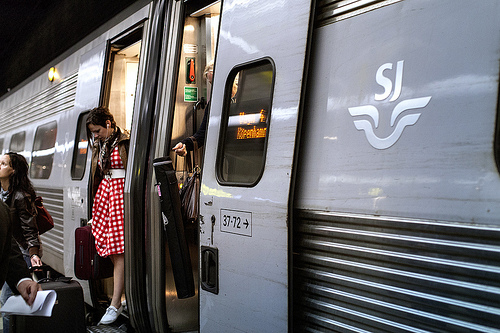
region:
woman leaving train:
[0, 150, 75, 265]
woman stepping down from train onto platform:
[61, 89, 143, 306]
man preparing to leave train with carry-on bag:
[161, 48, 227, 270]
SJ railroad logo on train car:
[342, 38, 447, 167]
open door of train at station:
[180, 32, 266, 319]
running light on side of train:
[34, 51, 76, 97]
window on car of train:
[22, 107, 77, 205]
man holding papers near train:
[4, 237, 87, 323]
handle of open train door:
[187, 230, 245, 315]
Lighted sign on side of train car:
[228, 101, 300, 159]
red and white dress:
[82, 145, 125, 263]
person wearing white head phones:
[90, 118, 120, 162]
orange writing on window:
[220, 96, 270, 163]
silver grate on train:
[328, 215, 476, 329]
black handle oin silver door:
[190, 236, 223, 324]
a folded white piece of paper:
[4, 277, 64, 314]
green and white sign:
[164, 74, 214, 115]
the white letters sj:
[327, 52, 439, 164]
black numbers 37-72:
[190, 200, 251, 263]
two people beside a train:
[5, 78, 150, 281]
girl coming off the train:
[40, 57, 165, 326]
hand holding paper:
[6, 262, 61, 321]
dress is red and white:
[78, 122, 148, 312]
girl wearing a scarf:
[65, 110, 130, 177]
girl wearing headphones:
[75, 99, 119, 157]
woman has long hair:
[0, 144, 50, 217]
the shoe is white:
[81, 288, 143, 330]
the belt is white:
[79, 160, 141, 190]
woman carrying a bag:
[1, 181, 70, 241]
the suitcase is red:
[62, 204, 127, 286]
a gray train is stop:
[3, 1, 498, 318]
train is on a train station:
[5, 4, 497, 331]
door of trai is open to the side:
[190, 0, 319, 327]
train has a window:
[211, 34, 283, 210]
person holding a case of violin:
[148, 60, 220, 314]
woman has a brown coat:
[74, 101, 141, 330]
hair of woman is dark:
[74, 102, 135, 175]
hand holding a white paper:
[0, 210, 65, 327]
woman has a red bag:
[2, 140, 64, 270]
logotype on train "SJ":
[337, 49, 437, 159]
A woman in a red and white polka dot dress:
[78, 107, 130, 318]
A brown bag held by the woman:
[63, 206, 116, 278]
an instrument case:
[155, 155, 200, 310]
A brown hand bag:
[176, 137, 208, 222]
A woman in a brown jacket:
[1, 142, 61, 282]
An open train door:
[136, 3, 236, 331]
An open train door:
[95, 34, 140, 313]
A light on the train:
[37, 63, 64, 83]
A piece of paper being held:
[1, 285, 62, 320]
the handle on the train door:
[197, 239, 220, 300]